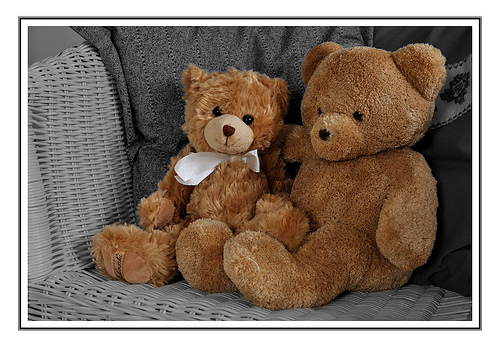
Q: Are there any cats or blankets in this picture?
A: Yes, there is a blanket.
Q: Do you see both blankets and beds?
A: No, there is a blanket but no beds.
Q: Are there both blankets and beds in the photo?
A: No, there is a blanket but no beds.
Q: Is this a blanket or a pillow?
A: This is a blanket.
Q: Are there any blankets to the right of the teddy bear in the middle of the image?
A: Yes, there is a blanket to the right of the teddy bear.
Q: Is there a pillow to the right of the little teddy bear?
A: No, there is a blanket to the right of the teddy bear.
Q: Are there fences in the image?
A: No, there are no fences.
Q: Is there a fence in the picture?
A: No, there are no fences.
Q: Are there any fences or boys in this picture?
A: No, there are no fences or boys.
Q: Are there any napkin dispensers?
A: No, there are no napkin dispensers.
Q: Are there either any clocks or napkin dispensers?
A: No, there are no napkin dispensers or clocks.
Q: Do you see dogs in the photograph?
A: No, there are no dogs.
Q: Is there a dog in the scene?
A: No, there are no dogs.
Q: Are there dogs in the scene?
A: No, there are no dogs.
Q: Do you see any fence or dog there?
A: No, there are no dogs or fences.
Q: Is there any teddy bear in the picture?
A: Yes, there is a teddy bear.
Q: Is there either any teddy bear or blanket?
A: Yes, there is a teddy bear.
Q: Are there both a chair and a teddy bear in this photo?
A: Yes, there are both a teddy bear and a chair.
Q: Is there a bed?
A: No, there are no beds.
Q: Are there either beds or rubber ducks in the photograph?
A: No, there are no beds or rubber ducks.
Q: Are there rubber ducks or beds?
A: No, there are no beds or rubber ducks.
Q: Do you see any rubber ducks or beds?
A: No, there are no beds or rubber ducks.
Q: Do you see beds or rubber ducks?
A: No, there are no beds or rubber ducks.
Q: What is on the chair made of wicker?
A: The teddy bear is on the chair.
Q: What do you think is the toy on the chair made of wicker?
A: The toy is a teddy bear.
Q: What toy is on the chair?
A: The toy is a teddy bear.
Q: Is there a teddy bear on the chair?
A: Yes, there is a teddy bear on the chair.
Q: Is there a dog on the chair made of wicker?
A: No, there is a teddy bear on the chair.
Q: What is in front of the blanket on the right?
A: The teddy bear is in front of the blanket.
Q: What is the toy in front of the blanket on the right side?
A: The toy is a teddy bear.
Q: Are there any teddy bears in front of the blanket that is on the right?
A: Yes, there is a teddy bear in front of the blanket.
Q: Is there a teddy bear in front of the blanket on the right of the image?
A: Yes, there is a teddy bear in front of the blanket.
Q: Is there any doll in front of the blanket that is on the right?
A: No, there is a teddy bear in front of the blanket.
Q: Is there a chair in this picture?
A: Yes, there is a chair.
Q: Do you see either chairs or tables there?
A: Yes, there is a chair.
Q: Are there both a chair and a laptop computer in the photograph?
A: No, there is a chair but no laptops.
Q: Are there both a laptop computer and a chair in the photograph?
A: No, there is a chair but no laptops.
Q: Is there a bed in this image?
A: No, there are no beds.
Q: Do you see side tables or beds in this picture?
A: No, there are no beds or side tables.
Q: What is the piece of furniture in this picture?
A: The piece of furniture is a chair.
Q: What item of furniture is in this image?
A: The piece of furniture is a chair.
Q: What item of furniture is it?
A: The piece of furniture is a chair.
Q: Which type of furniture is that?
A: This is a chair.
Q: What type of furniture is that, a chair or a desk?
A: This is a chair.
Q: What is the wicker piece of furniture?
A: The piece of furniture is a chair.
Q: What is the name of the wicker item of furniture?
A: The piece of furniture is a chair.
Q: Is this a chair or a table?
A: This is a chair.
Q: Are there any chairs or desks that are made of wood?
A: No, there is a chair but it is made of wicker.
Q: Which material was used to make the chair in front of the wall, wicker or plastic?
A: The chair is made of wicker.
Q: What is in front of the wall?
A: The chair is in front of the wall.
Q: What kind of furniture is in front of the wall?
A: The piece of furniture is a chair.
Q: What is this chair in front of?
A: The chair is in front of the wall.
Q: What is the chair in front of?
A: The chair is in front of the wall.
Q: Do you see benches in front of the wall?
A: No, there is a chair in front of the wall.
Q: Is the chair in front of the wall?
A: Yes, the chair is in front of the wall.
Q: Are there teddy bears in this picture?
A: Yes, there is a teddy bear.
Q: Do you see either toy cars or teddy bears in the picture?
A: Yes, there is a teddy bear.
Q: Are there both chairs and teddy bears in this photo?
A: Yes, there are both a teddy bear and a chair.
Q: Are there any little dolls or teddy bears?
A: Yes, there is a little teddy bear.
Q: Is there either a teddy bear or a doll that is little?
A: Yes, the teddy bear is little.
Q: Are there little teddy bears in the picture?
A: Yes, there is a little teddy bear.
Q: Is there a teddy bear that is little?
A: Yes, there is a teddy bear that is little.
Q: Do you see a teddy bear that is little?
A: Yes, there is a teddy bear that is little.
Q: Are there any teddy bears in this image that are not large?
A: Yes, there is a little teddy bear.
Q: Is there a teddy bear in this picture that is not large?
A: Yes, there is a little teddy bear.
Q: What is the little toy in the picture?
A: The toy is a teddy bear.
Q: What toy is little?
A: The toy is a teddy bear.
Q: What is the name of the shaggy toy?
A: The toy is a teddy bear.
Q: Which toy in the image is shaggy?
A: The toy is a teddy bear.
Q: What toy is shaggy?
A: The toy is a teddy bear.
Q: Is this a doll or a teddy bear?
A: This is a teddy bear.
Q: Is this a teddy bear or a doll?
A: This is a teddy bear.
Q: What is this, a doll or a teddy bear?
A: This is a teddy bear.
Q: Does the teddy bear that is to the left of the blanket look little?
A: Yes, the teddy bear is little.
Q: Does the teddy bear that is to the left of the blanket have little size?
A: Yes, the teddy bear is little.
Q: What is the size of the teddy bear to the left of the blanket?
A: The teddy bear is little.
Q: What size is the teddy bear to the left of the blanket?
A: The teddy bear is little.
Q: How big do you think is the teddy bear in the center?
A: The teddy bear is little.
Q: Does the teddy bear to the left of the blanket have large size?
A: No, the teddy bear is little.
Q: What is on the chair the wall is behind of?
A: The teddy bear is on the chair.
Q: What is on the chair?
A: The teddy bear is on the chair.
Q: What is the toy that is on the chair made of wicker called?
A: The toy is a teddy bear.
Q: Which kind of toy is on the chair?
A: The toy is a teddy bear.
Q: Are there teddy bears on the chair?
A: Yes, there is a teddy bear on the chair.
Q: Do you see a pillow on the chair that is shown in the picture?
A: No, there is a teddy bear on the chair.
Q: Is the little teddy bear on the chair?
A: Yes, the teddy bear is on the chair.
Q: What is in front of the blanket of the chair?
A: The teddy bear is in front of the blanket.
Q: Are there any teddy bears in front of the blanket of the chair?
A: Yes, there is a teddy bear in front of the blanket.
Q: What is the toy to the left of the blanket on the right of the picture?
A: The toy is a teddy bear.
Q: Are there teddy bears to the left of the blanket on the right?
A: Yes, there is a teddy bear to the left of the blanket.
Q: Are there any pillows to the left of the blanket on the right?
A: No, there is a teddy bear to the left of the blanket.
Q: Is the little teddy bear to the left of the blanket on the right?
A: Yes, the teddy bear is to the left of the blanket.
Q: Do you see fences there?
A: No, there are no fences.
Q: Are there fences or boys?
A: No, there are no fences or boys.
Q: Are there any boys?
A: No, there are no boys.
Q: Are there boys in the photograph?
A: No, there are no boys.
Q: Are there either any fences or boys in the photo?
A: No, there are no boys or fences.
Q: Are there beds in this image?
A: No, there are no beds.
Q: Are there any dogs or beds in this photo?
A: No, there are no beds or dogs.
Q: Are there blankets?
A: Yes, there is a blanket.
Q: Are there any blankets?
A: Yes, there is a blanket.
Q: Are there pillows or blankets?
A: Yes, there is a blanket.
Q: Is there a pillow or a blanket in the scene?
A: Yes, there is a blanket.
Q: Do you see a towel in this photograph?
A: No, there are no towels.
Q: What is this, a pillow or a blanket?
A: This is a blanket.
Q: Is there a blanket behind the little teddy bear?
A: Yes, there is a blanket behind the teddy bear.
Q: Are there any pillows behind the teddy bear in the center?
A: No, there is a blanket behind the teddy bear.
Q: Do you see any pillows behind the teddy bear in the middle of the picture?
A: No, there is a blanket behind the teddy bear.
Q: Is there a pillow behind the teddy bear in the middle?
A: No, there is a blanket behind the teddy bear.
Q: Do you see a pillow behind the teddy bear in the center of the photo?
A: No, there is a blanket behind the teddy bear.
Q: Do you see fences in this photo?
A: No, there are no fences.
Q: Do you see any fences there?
A: No, there are no fences.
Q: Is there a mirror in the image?
A: No, there are no mirrors.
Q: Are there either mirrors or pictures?
A: No, there are no mirrors or pictures.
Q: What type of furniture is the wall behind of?
A: The wall is behind the chair.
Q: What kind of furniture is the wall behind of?
A: The wall is behind the chair.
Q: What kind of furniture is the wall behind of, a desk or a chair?
A: The wall is behind a chair.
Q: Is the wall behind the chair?
A: Yes, the wall is behind the chair.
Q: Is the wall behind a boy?
A: No, the wall is behind the chair.